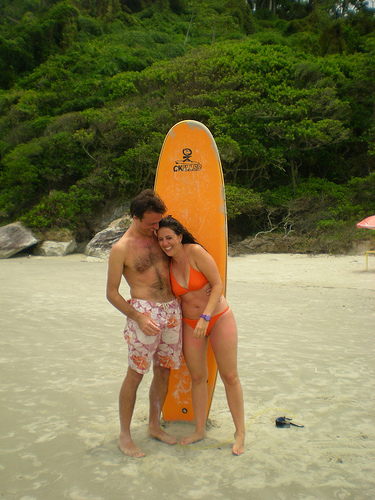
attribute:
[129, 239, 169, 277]
chest — hairy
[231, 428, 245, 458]
foot — bare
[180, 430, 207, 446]
foot — bare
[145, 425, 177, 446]
foot — bare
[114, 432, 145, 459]
foot — bare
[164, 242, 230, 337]
bikini — orange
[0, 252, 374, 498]
sand — white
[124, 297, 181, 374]
swim trunks — floral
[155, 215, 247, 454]
woman — standing, young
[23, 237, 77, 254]
rock — large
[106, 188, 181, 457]
man — standing, young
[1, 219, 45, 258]
rock — large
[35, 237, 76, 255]
rock — large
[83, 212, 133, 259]
rock — large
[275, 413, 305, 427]
strap — black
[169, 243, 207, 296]
bikini top — orange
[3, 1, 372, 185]
trees — background, green, very green, leafy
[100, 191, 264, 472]
couple — barefoot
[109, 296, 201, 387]
swim trunks — Hawaiian print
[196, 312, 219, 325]
watch — purple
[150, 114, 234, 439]
surfboard — orange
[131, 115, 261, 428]
yellow surfboard — orangish yellow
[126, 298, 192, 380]
man's trunks — floral, swimming trunks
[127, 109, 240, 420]
surfboard — orange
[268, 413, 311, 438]
object — black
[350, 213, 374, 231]
an umbrella — orange